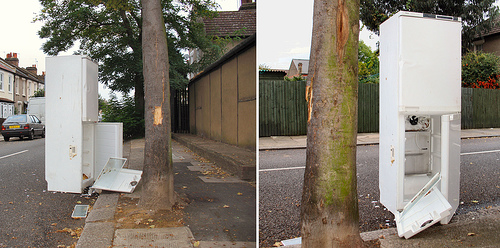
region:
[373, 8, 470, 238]
extremely broken white refrigerator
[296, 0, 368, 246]
very thick tree trunk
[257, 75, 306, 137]
tall green fencing covering house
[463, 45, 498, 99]
beautiful bushes and roses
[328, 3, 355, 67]
hole in tree trunk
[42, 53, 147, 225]
white refrigerator in multiple pieces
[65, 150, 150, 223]
scrap white pieces on the ground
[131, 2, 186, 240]
tree trunk on sidewalk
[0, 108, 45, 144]
car driving down road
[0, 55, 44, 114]
multiple houses close together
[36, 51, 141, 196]
A broken fridge outside on the road.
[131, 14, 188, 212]
The trunk of the tree.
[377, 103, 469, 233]
The door of the fridge is broken off.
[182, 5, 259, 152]
A house in the back ground.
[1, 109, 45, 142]
A gray car in the back ground.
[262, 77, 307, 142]
A tall green fence in the background.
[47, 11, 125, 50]
A bunch of leaves in the back ground.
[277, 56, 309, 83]
A house behind the big green fence.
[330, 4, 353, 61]
A hole in the tree.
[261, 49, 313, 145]
The house and the big green fence together.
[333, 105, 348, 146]
part of a stem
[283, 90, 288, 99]
part of a fence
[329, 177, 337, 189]
part of a tree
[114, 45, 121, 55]
part of a branch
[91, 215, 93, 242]
edge of a road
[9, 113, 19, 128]
back of a car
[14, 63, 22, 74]
part of a building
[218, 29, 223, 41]
edge of a roof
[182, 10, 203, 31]
part of a leaf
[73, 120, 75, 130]
part of a fridge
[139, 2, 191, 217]
This is a trunk a tree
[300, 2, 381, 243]
This is a trunk a tree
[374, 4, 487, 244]
This is a fridge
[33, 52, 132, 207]
This is a fridge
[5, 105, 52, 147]
This is a car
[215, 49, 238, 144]
This is a door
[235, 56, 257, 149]
This is a door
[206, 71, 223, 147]
This is a door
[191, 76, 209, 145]
This is a door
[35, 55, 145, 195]
Refrigerator in the street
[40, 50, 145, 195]
Old refrigerator in the street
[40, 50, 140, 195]
Broken refrigerator in the street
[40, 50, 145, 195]
White refrigerator in the street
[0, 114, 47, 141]
Car is parked on the street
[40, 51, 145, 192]
Old white refrigerator in the street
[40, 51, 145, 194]
Broken old refrigerator in the street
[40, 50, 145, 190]
Broken white refrigerator in the street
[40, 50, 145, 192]
Refrigerator sitting next to curb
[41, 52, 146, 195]
Old refrigerator sitting next to curb